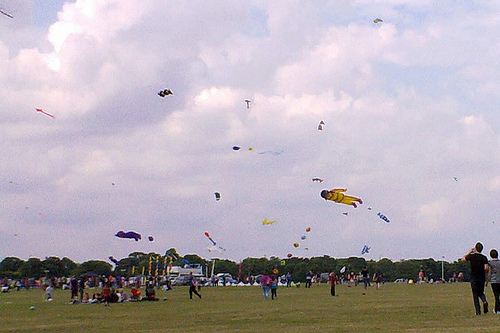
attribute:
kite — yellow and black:
[319, 186, 365, 209]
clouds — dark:
[0, 2, 500, 261]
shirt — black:
[464, 254, 487, 288]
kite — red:
[29, 100, 53, 121]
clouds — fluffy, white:
[45, 5, 150, 119]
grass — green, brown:
[363, 286, 435, 329]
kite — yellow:
[312, 183, 374, 210]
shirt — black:
[459, 251, 494, 280]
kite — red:
[25, 96, 76, 127]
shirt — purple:
[257, 272, 292, 294]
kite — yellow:
[253, 215, 275, 229]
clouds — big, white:
[40, 40, 322, 187]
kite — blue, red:
[193, 224, 240, 264]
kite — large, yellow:
[314, 178, 367, 218]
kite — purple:
[107, 223, 170, 253]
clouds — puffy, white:
[93, 38, 460, 205]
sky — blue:
[23, 30, 498, 303]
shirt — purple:
[260, 272, 281, 293]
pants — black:
[182, 289, 203, 299]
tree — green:
[0, 200, 497, 280]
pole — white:
[436, 214, 447, 285]